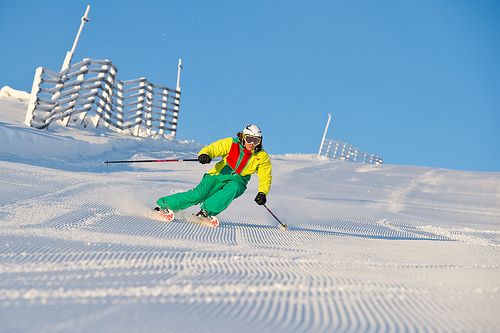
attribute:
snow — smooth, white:
[5, 81, 492, 326]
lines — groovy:
[11, 222, 403, 325]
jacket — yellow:
[196, 139, 275, 201]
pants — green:
[156, 169, 249, 218]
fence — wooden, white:
[23, 59, 184, 143]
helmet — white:
[239, 123, 265, 149]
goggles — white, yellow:
[242, 132, 261, 147]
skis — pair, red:
[155, 204, 225, 230]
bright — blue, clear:
[4, 5, 494, 174]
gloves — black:
[197, 151, 212, 164]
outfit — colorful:
[157, 122, 273, 229]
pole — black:
[105, 151, 209, 168]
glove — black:
[252, 191, 269, 205]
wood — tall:
[167, 53, 189, 141]